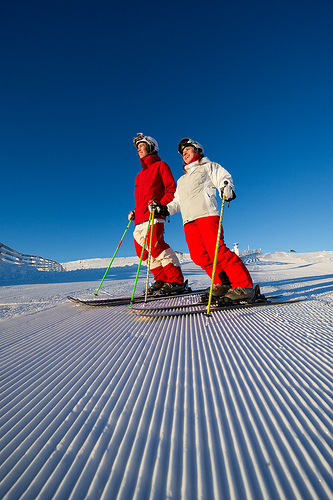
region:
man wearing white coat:
[185, 177, 199, 205]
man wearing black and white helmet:
[172, 136, 200, 141]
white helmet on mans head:
[130, 129, 156, 143]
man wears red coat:
[137, 173, 150, 190]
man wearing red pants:
[199, 224, 206, 238]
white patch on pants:
[134, 226, 141, 235]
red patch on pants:
[150, 225, 152, 234]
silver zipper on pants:
[150, 230, 157, 245]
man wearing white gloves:
[225, 186, 234, 198]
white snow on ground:
[201, 362, 236, 397]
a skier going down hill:
[139, 136, 304, 313]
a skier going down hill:
[67, 130, 217, 306]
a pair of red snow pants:
[176, 213, 255, 291]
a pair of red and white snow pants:
[127, 220, 183, 288]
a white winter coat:
[165, 158, 230, 222]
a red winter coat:
[130, 157, 174, 224]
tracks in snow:
[0, 271, 324, 498]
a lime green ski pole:
[87, 213, 132, 296]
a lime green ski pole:
[124, 212, 152, 307]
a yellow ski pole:
[201, 190, 227, 315]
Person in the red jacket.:
[123, 132, 191, 298]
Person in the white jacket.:
[159, 133, 266, 302]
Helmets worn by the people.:
[126, 129, 206, 147]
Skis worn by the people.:
[58, 283, 309, 321]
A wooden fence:
[0, 239, 68, 270]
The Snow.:
[0, 247, 331, 497]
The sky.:
[0, 0, 331, 260]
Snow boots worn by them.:
[143, 277, 267, 305]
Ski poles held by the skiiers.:
[92, 190, 225, 323]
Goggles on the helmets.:
[130, 132, 193, 152]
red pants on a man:
[182, 215, 255, 286]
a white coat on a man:
[169, 158, 234, 217]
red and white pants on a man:
[132, 221, 183, 284]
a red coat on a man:
[133, 152, 177, 224]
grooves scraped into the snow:
[0, 297, 331, 498]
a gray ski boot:
[223, 288, 253, 298]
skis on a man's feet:
[66, 279, 211, 309]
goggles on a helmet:
[131, 131, 145, 144]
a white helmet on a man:
[133, 132, 160, 156]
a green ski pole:
[92, 211, 136, 299]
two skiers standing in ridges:
[66, 105, 290, 327]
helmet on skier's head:
[123, 125, 159, 155]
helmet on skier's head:
[175, 132, 208, 163]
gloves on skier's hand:
[206, 176, 235, 204]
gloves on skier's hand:
[153, 198, 173, 218]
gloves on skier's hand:
[122, 208, 136, 224]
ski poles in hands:
[134, 216, 147, 309]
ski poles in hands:
[219, 186, 225, 322]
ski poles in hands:
[98, 225, 126, 279]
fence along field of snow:
[4, 248, 66, 275]